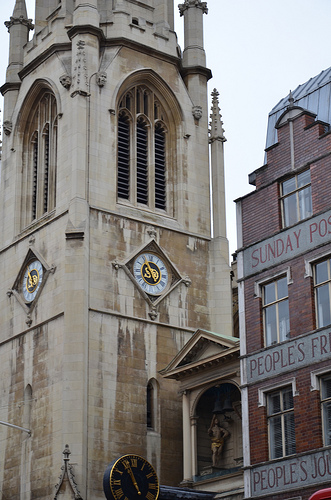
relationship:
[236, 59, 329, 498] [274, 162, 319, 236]
building has window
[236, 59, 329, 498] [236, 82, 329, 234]
building has top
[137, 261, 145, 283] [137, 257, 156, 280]
numbers aer gold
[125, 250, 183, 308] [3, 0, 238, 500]
clock on building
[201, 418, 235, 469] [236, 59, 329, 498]
statue on building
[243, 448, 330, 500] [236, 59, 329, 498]
sign on building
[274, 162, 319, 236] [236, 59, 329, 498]
window in building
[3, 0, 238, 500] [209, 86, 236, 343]
building has spire